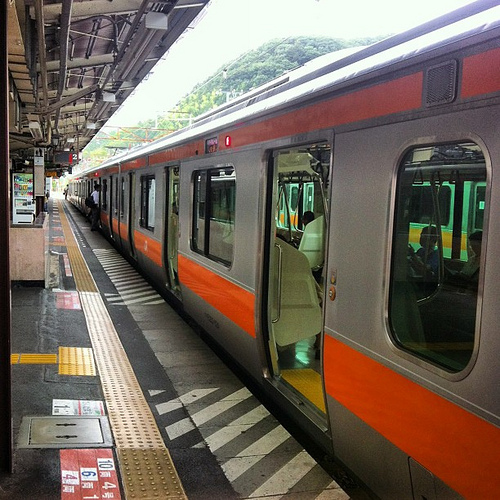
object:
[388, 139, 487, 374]
window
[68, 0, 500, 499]
train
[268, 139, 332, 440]
door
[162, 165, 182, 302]
door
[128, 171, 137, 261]
door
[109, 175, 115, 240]
door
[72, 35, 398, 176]
mountainside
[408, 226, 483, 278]
people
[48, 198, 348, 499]
boarding ramp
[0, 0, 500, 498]
train station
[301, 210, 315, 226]
man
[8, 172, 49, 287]
booth